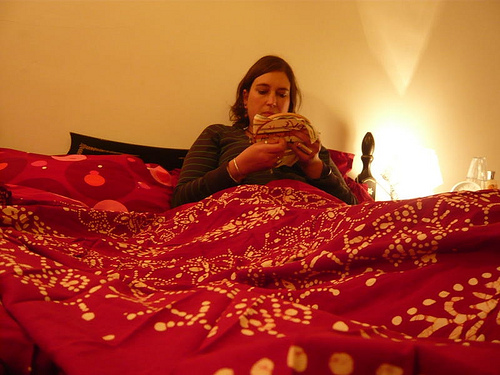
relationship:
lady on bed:
[170, 54, 360, 210] [46, 0, 403, 202]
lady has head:
[170, 54, 360, 210] [217, 31, 302, 123]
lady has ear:
[170, 54, 360, 210] [241, 88, 250, 108]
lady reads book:
[170, 54, 360, 210] [253, 110, 308, 163]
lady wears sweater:
[170, 54, 360, 210] [169, 107, 361, 230]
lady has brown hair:
[170, 54, 360, 210] [234, 54, 301, 121]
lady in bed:
[170, 54, 360, 210] [1, 143, 499, 372]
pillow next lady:
[0, 146, 178, 211] [170, 54, 360, 210]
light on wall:
[373, 127, 445, 203] [4, 4, 497, 204]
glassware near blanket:
[465, 156, 487, 193] [4, 184, 496, 373]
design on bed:
[212, 279, 322, 344] [16, 161, 487, 373]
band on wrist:
[232, 158, 242, 175] [229, 152, 257, 189]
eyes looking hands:
[241, 73, 297, 110] [228, 134, 333, 181]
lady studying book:
[170, 54, 360, 210] [253, 111, 322, 168]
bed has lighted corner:
[54, 91, 469, 357] [342, 140, 467, 255]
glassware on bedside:
[465, 156, 499, 190] [361, 141, 484, 218]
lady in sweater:
[170, 54, 360, 210] [165, 122, 352, 200]